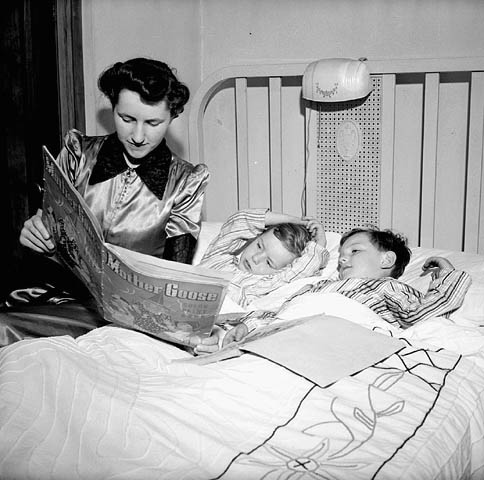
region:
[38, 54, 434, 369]
a woman reading to children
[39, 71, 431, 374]
a mother and her boys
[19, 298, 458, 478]
a white and black blanket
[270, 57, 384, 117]
a lamp on the bed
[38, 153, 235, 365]
a mother goose book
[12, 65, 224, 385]
a woman in a dress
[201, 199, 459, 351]
two boys in stripped shirts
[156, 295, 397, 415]
another open book across boy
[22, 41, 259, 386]
a woman reading a book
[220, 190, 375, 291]
hands above his head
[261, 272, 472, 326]
striped boys pajama top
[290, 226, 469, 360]
boy laying in bed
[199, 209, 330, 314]
boy wearing pajamas in bed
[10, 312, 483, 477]
white and black comforter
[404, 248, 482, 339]
white pillow on bed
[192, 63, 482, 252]
white headboard on bed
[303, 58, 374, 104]
light hanging on headboard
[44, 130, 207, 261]
silk button down shirt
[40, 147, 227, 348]
fairy tale book in hand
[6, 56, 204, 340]
woman sitting on bed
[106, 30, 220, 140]
woman has dark hair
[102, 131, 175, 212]
woman has dark collar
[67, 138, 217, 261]
woman has shiny blouse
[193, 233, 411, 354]
two children in bed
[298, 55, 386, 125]
light is above bed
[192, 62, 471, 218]
white rails on bed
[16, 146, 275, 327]
woman reads from book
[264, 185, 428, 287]
children have dark hair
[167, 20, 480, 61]
light wall behind bed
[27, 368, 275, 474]
light blanket on bed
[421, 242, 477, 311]
left arm on boy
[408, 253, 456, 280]
left hand on boy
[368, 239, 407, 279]
left ear on boy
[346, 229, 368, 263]
left eye on boy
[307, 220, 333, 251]
left hand on child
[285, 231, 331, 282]
left arm on child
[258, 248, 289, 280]
left eye on child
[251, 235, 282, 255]
right eye on child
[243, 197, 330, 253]
right hand on child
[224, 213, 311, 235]
right arm on child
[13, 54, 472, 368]
Woman holds book up for children in bed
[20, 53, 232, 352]
Woman holds Mother Goose book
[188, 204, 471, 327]
Two kids lay in a bed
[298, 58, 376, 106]
Reading lamp on the headboard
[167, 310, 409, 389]
Book rests on kids legs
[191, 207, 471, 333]
Kids interested in book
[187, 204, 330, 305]
Kid relaxes in bed with hands over head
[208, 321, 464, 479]
Floral pattern on bed cover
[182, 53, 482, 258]
Antique bed headboard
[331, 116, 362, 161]
Decorative emblem on headboard